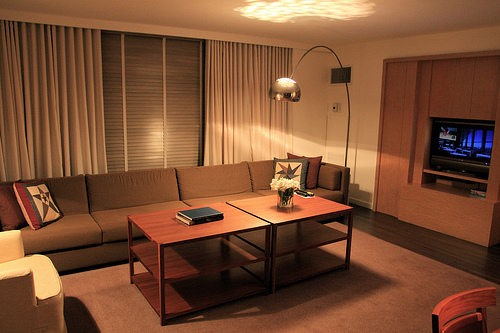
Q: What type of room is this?
A: It is a living room.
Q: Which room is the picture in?
A: It is at the living room.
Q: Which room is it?
A: It is a living room.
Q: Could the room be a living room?
A: Yes, it is a living room.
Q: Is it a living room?
A: Yes, it is a living room.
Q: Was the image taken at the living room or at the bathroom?
A: It was taken at the living room.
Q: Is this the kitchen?
A: No, it is the living room.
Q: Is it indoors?
A: Yes, it is indoors.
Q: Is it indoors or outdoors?
A: It is indoors.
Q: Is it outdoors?
A: No, it is indoors.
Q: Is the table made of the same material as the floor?
A: Yes, both the table and the floor are made of wood.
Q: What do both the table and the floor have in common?
A: The material, both the table and the floor are wooden.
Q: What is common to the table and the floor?
A: The material, both the table and the floor are wooden.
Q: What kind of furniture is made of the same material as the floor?
A: The table is made of the same material as the floor.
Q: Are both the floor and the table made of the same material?
A: Yes, both the floor and the table are made of wood.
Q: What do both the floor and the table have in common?
A: The material, both the floor and the table are wooden.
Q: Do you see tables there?
A: Yes, there is a table.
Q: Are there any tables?
A: Yes, there is a table.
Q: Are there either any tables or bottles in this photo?
A: Yes, there is a table.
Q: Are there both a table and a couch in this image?
A: Yes, there are both a table and a couch.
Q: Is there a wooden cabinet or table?
A: Yes, there is a wood table.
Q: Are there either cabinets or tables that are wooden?
A: Yes, the table is wooden.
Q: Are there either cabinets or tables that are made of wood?
A: Yes, the table is made of wood.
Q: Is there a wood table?
A: Yes, there is a table that is made of wood.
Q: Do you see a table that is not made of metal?
A: Yes, there is a table that is made of wood.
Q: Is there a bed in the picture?
A: No, there are no beds.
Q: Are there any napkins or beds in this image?
A: No, there are no beds or napkins.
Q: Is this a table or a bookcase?
A: This is a table.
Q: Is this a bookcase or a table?
A: This is a table.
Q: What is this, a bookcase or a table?
A: This is a table.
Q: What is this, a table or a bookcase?
A: This is a table.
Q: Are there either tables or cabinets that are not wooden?
A: No, there is a table but it is wooden.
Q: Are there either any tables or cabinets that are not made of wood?
A: No, there is a table but it is made of wood.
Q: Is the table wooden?
A: Yes, the table is wooden.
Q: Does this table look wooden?
A: Yes, the table is wooden.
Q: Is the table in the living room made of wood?
A: Yes, the table is made of wood.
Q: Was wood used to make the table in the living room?
A: Yes, the table is made of wood.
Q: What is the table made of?
A: The table is made of wood.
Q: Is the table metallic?
A: No, the table is wooden.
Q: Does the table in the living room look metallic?
A: No, the table is wooden.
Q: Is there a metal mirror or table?
A: No, there is a table but it is wooden.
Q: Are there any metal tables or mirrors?
A: No, there is a table but it is wooden.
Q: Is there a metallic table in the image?
A: No, there is a table but it is wooden.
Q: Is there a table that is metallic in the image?
A: No, there is a table but it is wooden.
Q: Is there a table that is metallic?
A: No, there is a table but it is wooden.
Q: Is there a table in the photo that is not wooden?
A: No, there is a table but it is wooden.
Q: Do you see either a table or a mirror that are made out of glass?
A: No, there is a table but it is made of wood.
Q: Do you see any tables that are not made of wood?
A: No, there is a table but it is made of wood.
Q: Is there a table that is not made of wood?
A: No, there is a table but it is made of wood.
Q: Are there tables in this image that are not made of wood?
A: No, there is a table but it is made of wood.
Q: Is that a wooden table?
A: Yes, that is a wooden table.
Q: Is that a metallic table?
A: No, that is a wooden table.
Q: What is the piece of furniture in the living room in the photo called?
A: The piece of furniture is a table.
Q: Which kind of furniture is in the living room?
A: The piece of furniture is a table.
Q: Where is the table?
A: The table is in the living room.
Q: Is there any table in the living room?
A: Yes, there is a table in the living room.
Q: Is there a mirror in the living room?
A: No, there is a table in the living room.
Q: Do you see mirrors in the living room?
A: No, there is a table in the living room.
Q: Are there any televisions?
A: Yes, there is a television.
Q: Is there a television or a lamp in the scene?
A: Yes, there is a television.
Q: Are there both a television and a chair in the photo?
A: Yes, there are both a television and a chair.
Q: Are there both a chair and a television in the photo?
A: Yes, there are both a television and a chair.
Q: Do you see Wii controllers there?
A: No, there are no Wii controllers.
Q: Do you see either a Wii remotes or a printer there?
A: No, there are no Wii controllers or printers.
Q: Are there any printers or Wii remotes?
A: No, there are no Wii remotes or printers.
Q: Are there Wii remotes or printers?
A: No, there are no Wii remotes or printers.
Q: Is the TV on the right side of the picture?
A: Yes, the TV is on the right of the image.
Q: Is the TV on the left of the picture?
A: No, the TV is on the right of the image.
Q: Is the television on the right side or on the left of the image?
A: The television is on the right of the image.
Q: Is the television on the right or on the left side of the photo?
A: The television is on the right of the image.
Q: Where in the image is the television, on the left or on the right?
A: The television is on the right of the image.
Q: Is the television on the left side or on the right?
A: The television is on the right of the image.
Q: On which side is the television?
A: The television is on the right of the image.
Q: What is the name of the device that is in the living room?
A: The device is a television.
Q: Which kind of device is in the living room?
A: The device is a television.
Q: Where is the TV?
A: The TV is in the living room.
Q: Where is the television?
A: The TV is in the living room.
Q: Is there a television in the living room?
A: Yes, there is a television in the living room.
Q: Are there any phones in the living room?
A: No, there is a television in the living room.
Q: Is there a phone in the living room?
A: No, there is a television in the living room.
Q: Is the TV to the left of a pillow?
A: No, the TV is to the right of a pillow.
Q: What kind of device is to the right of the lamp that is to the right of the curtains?
A: The device is a television.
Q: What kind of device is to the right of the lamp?
A: The device is a television.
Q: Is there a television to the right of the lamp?
A: Yes, there is a television to the right of the lamp.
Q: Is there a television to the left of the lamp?
A: No, the television is to the right of the lamp.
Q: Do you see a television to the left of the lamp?
A: No, the television is to the right of the lamp.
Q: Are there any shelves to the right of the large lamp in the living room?
A: No, there is a television to the right of the lamp.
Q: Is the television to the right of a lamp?
A: Yes, the television is to the right of a lamp.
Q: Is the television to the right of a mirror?
A: No, the television is to the right of a lamp.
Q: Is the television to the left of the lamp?
A: No, the television is to the right of the lamp.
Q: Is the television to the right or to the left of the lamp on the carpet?
A: The television is to the right of the lamp.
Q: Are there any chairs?
A: Yes, there is a chair.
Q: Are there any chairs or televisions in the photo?
A: Yes, there is a chair.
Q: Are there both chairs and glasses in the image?
A: No, there is a chair but no glasses.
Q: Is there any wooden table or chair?
A: Yes, there is a wood chair.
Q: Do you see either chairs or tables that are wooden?
A: Yes, the chair is wooden.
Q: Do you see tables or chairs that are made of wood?
A: Yes, the chair is made of wood.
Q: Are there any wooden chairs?
A: Yes, there is a wood chair.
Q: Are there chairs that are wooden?
A: Yes, there is a chair that is wooden.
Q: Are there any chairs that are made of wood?
A: Yes, there is a chair that is made of wood.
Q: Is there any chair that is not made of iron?
A: Yes, there is a chair that is made of wood.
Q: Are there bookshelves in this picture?
A: No, there are no bookshelves.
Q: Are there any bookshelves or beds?
A: No, there are no bookshelves or beds.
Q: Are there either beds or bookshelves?
A: No, there are no bookshelves or beds.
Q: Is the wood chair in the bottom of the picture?
A: Yes, the chair is in the bottom of the image.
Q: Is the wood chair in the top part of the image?
A: No, the chair is in the bottom of the image.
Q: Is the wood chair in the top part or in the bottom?
A: The chair is in the bottom of the image.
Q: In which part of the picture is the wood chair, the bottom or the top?
A: The chair is in the bottom of the image.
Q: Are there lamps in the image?
A: Yes, there is a lamp.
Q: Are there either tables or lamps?
A: Yes, there is a lamp.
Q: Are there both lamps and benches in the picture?
A: No, there is a lamp but no benches.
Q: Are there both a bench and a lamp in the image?
A: No, there is a lamp but no benches.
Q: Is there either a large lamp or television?
A: Yes, there is a large lamp.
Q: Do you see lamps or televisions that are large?
A: Yes, the lamp is large.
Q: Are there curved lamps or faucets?
A: Yes, there is a curved lamp.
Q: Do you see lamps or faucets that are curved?
A: Yes, the lamp is curved.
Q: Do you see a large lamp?
A: Yes, there is a large lamp.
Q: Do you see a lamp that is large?
A: Yes, there is a lamp that is large.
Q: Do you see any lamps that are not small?
A: Yes, there is a large lamp.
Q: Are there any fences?
A: No, there are no fences.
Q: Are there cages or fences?
A: No, there are no fences or cages.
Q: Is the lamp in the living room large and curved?
A: Yes, the lamp is large and curved.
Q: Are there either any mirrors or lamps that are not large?
A: No, there is a lamp but it is large.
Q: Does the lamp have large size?
A: Yes, the lamp is large.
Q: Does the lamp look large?
A: Yes, the lamp is large.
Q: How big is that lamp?
A: The lamp is large.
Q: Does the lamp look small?
A: No, the lamp is large.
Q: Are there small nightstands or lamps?
A: No, there is a lamp but it is large.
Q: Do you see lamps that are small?
A: No, there is a lamp but it is large.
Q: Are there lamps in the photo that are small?
A: No, there is a lamp but it is large.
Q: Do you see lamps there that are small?
A: No, there is a lamp but it is large.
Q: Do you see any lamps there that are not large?
A: No, there is a lamp but it is large.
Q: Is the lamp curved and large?
A: Yes, the lamp is curved and large.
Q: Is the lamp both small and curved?
A: No, the lamp is curved but large.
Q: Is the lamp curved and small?
A: No, the lamp is curved but large.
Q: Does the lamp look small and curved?
A: No, the lamp is curved but large.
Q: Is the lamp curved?
A: Yes, the lamp is curved.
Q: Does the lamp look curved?
A: Yes, the lamp is curved.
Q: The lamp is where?
A: The lamp is in the living room.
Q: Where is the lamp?
A: The lamp is in the living room.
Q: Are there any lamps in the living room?
A: Yes, there is a lamp in the living room.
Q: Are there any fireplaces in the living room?
A: No, there is a lamp in the living room.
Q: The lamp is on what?
A: The lamp is on the carpet.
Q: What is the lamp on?
A: The lamp is on the carpet.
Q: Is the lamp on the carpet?
A: Yes, the lamp is on the carpet.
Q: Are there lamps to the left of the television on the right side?
A: Yes, there is a lamp to the left of the TV.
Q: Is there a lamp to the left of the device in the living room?
A: Yes, there is a lamp to the left of the TV.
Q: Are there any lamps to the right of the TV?
A: No, the lamp is to the left of the TV.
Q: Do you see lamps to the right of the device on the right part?
A: No, the lamp is to the left of the TV.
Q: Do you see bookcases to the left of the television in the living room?
A: No, there is a lamp to the left of the TV.